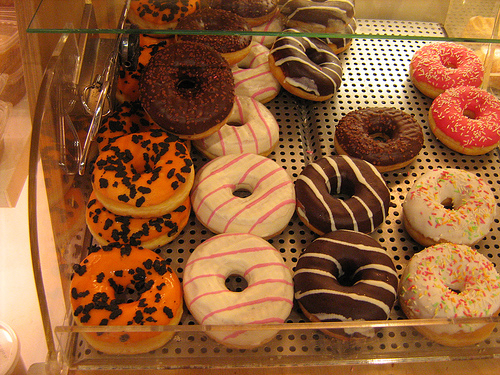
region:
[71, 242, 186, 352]
orange frosted donut with sprinkles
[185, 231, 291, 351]
pink and white frosted donut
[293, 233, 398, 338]
chocolate frosted striped donut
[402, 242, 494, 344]
white frosted donut with sprinkles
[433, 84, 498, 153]
pink frosted donut with sprinkles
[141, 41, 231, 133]
chocolate frosted donut with coconut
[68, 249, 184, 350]
chocolate sprinkles on donut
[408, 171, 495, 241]
pastel sprinkles on donut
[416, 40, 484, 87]
white sprinkles on donut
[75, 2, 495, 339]
donuts in glass case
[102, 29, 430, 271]
doughnuts are delicious food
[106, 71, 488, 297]
Different varities of donuts are placed.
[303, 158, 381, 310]
Brown donuts with white lines.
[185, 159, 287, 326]
White donuts with pink lines.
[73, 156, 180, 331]
Orange donuts with brown chips.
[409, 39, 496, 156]
Pink donuts and candy on top of it.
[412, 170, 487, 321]
White donuts with candy on top of it.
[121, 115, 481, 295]
Donuts are placed in tray.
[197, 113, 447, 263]
tray has holes in it.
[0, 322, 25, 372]
Trash is white color.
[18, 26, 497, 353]
Picture is taken in the store.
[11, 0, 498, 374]
Assorted doughnuts in a display case.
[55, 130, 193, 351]
Three doughnuts with orange frosting and chocolate sprinkles.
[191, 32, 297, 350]
Four doughnuts with white frosting and pink stripes.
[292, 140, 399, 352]
Two doughnuts with chocolate frosting and white stripes.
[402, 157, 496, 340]
White frosted doughnuts with pink and yellow sprinkles.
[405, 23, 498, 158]
Two doughnuts with pink frosting and coconut sprinkles.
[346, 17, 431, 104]
Silver tin with holes underneath doughnuts.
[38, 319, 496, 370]
Front of plastic display case.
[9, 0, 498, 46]
Glass top of display rack.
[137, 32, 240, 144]
Chocolate frosted doughnut.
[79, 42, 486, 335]
assorted donuts on display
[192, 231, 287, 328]
white frosting with pink stripes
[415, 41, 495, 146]
pink frosting with white sprinkles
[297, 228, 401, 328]
chocolate frosting with white stripes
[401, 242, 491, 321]
white frosting with sprinkles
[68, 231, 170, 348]
choclate chips on glaze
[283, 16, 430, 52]
glass shelf on display case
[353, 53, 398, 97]
holes in display rack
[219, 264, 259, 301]
hole in middle of donut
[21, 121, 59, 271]
curved side of display case